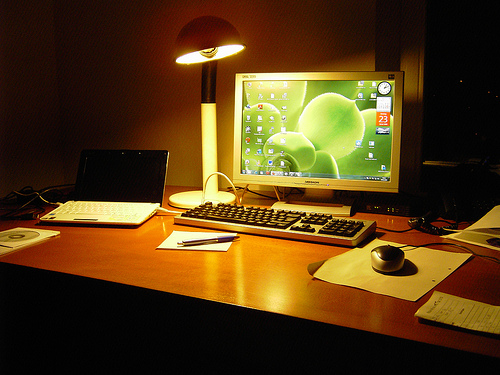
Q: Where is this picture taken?
A: An office.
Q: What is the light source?
A: A desk lamp.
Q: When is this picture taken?
A: Night time.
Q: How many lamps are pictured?
A: One.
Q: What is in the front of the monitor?
A: A keyboard.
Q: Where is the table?
A: On the desk.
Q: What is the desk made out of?
A: Wood.